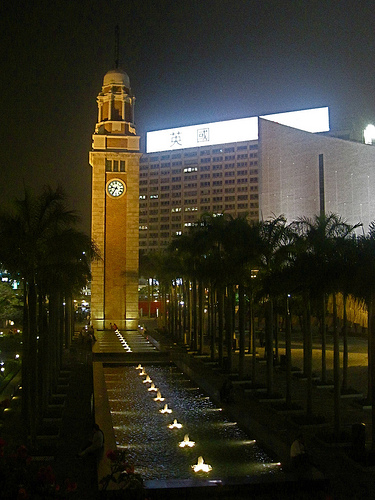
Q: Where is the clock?
A: On tower.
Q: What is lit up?
A: A row of lights on ground.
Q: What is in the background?
A: Building.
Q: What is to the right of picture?
A: Trees.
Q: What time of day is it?
A: After dark.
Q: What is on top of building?
A: Lit up sign.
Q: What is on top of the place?
A: Lighted sign.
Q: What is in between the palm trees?
A: Light in pool.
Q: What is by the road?
A: Tree trunks.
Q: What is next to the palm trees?
A: Pool of water.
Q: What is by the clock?
A: Tree tops.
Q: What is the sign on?
A: Building.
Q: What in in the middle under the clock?
A: Lights in water.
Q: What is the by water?
A: Clock in middle of tower.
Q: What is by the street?
A: Row of trees.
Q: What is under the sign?
A: Building with windows.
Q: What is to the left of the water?
A: Trees.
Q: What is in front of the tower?
A: Water.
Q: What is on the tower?
A: Clock.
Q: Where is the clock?
A: On tower.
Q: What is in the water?
A: Lights.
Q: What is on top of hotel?
A: Digital sign.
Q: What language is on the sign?
A: Japanese.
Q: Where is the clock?
A: On building.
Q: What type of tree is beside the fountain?
A: Palm trees.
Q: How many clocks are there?
A: 1.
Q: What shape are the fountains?
A: Rectangle.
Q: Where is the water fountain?
A: In front of clock building.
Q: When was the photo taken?
A: Night time.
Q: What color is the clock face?
A: White.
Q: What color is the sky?
A: Black.